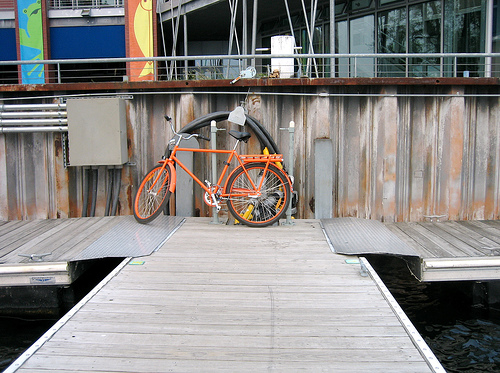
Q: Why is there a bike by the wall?
A: Parked.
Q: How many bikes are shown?
A: One.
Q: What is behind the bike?
A: A wall.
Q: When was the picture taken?
A: Daytime.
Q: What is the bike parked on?
A: A pier.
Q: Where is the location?
A: Dock.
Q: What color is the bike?
A: Orange.